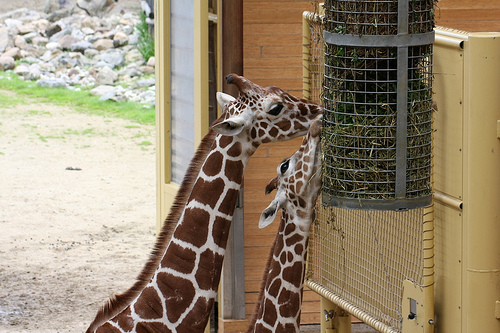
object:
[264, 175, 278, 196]
right ear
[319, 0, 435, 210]
basket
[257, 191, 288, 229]
ear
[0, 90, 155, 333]
ground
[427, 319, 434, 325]
bolt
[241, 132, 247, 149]
white area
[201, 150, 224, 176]
brown part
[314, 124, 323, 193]
jaw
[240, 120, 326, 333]
giraffes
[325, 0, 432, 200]
grass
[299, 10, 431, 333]
fence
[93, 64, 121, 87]
rocks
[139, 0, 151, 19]
white line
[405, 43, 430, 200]
mesh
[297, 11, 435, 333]
frame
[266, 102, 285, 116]
right eye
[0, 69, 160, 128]
grass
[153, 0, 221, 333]
door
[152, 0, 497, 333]
building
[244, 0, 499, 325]
wood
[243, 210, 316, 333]
neck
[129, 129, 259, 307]
neck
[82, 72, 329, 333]
giraffe